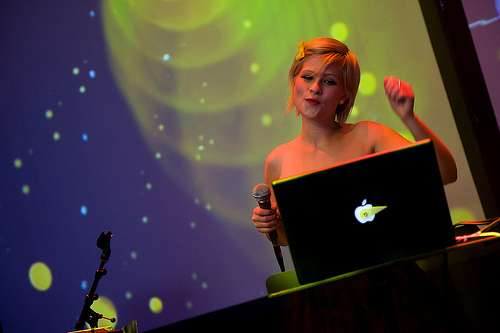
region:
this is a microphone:
[242, 187, 294, 269]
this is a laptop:
[270, 132, 452, 276]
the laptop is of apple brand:
[349, 195, 393, 228]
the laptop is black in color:
[303, 212, 325, 249]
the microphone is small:
[248, 185, 295, 269]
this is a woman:
[247, 27, 477, 265]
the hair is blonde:
[315, 41, 332, 52]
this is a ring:
[396, 77, 405, 91]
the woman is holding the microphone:
[248, 142, 340, 298]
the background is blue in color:
[60, 58, 203, 180]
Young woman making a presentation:
[232, 23, 478, 304]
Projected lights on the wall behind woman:
[1, 3, 496, 322]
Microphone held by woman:
[243, 178, 295, 276]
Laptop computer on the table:
[252, 128, 481, 302]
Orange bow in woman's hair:
[286, 33, 311, 63]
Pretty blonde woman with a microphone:
[238, 31, 448, 219]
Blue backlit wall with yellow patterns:
[6, 4, 232, 321]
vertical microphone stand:
[56, 222, 143, 332]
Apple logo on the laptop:
[348, 194, 392, 229]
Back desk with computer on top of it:
[261, 231, 498, 313]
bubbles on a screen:
[30, 52, 208, 193]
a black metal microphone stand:
[74, 220, 134, 320]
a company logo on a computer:
[332, 189, 416, 229]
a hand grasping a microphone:
[246, 203, 283, 233]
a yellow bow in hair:
[281, 34, 316, 62]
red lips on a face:
[301, 94, 328, 109]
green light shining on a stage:
[251, 11, 306, 56]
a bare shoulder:
[264, 145, 309, 164]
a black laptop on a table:
[287, 162, 424, 260]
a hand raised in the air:
[377, 73, 428, 114]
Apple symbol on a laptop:
[351, 199, 378, 222]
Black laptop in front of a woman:
[265, 161, 453, 263]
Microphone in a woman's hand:
[243, 181, 288, 273]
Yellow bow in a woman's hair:
[294, 37, 306, 58]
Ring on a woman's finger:
[392, 76, 403, 88]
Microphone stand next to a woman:
[63, 222, 145, 329]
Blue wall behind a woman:
[8, 15, 58, 86]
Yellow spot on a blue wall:
[22, 257, 55, 290]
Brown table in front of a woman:
[227, 280, 453, 332]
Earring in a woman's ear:
[336, 97, 346, 107]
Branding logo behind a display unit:
[352, 199, 386, 226]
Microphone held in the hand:
[248, 181, 282, 258]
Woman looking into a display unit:
[255, 28, 422, 148]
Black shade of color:
[366, 268, 496, 329]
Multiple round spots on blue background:
[15, 24, 234, 248]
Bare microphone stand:
[41, 219, 136, 330]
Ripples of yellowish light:
[115, 4, 252, 209]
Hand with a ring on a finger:
[381, 70, 418, 114]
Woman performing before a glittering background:
[8, 8, 491, 328]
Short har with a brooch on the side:
[281, 28, 362, 135]